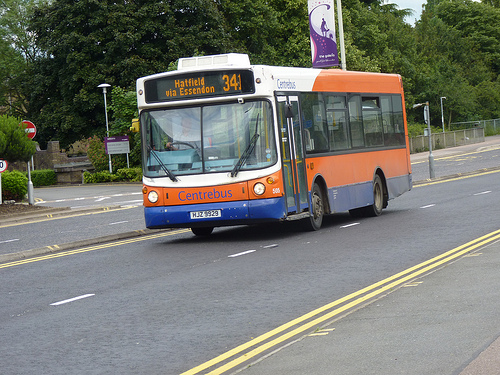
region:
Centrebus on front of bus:
[175, 187, 237, 206]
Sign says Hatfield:
[171, 74, 210, 91]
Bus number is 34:
[219, 71, 241, 96]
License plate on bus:
[188, 209, 221, 221]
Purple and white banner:
[304, 1, 341, 60]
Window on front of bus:
[141, 95, 280, 177]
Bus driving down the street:
[131, 53, 416, 232]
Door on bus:
[273, 92, 310, 214]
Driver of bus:
[166, 115, 200, 152]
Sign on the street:
[99, 131, 133, 176]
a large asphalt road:
[0, 147, 499, 374]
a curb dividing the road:
[0, 165, 498, 264]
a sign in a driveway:
[17, 120, 36, 205]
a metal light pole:
[97, 82, 112, 172]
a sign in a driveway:
[103, 135, 130, 168]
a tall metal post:
[335, 0, 345, 72]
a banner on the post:
[306, 0, 340, 67]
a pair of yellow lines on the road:
[179, 228, 499, 373]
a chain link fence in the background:
[407, 118, 498, 153]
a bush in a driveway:
[0, 169, 29, 201]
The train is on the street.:
[110, 57, 445, 247]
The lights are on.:
[141, 180, 278, 202]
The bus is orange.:
[148, 29, 435, 261]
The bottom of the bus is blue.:
[140, 179, 446, 225]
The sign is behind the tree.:
[14, 116, 44, 149]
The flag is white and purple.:
[303, 1, 353, 76]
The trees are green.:
[16, 9, 498, 148]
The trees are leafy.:
[47, 0, 489, 148]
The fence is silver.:
[409, 114, 496, 161]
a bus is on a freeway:
[132, 49, 416, 242]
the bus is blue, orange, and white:
[131, 60, 413, 232]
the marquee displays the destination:
[132, 66, 268, 98]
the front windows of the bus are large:
[136, 105, 281, 190]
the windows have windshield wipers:
[139, 110, 264, 183]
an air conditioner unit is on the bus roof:
[173, 50, 251, 72]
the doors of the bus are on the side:
[273, 87, 312, 219]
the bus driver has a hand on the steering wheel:
[158, 113, 205, 161]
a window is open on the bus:
[355, 90, 387, 122]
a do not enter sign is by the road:
[13, 115, 40, 167]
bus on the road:
[113, 38, 428, 259]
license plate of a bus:
[179, 205, 229, 226]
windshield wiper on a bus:
[224, 130, 269, 182]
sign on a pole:
[13, 114, 50, 207]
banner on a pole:
[294, 1, 362, 75]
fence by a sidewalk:
[406, 121, 481, 156]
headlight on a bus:
[247, 168, 272, 212]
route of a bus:
[151, 67, 248, 106]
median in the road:
[7, 223, 147, 269]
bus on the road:
[84, 21, 496, 335]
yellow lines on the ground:
[150, 233, 495, 363]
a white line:
[42, 274, 99, 317]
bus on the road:
[100, 51, 445, 250]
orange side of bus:
[274, 59, 409, 199]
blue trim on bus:
[139, 172, 416, 229]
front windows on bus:
[139, 109, 282, 180]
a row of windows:
[293, 90, 410, 150]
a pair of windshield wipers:
[134, 131, 270, 184]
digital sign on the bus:
[149, 72, 247, 100]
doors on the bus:
[268, 83, 316, 205]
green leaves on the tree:
[428, 48, 445, 68]